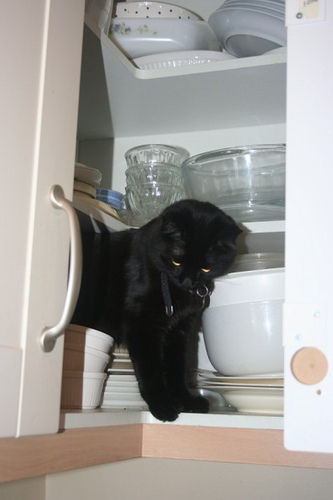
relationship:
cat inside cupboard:
[58, 193, 252, 427] [1, 6, 86, 481]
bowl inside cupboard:
[177, 142, 283, 226] [6, 6, 309, 497]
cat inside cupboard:
[58, 193, 252, 427] [27, 6, 321, 482]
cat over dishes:
[81, 175, 278, 452] [67, 327, 166, 409]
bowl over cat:
[190, 142, 279, 207] [76, 203, 229, 349]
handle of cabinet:
[48, 184, 82, 351] [86, 57, 302, 423]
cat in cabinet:
[58, 193, 252, 427] [1, 0, 332, 482]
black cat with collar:
[70, 199, 245, 421] [158, 270, 209, 316]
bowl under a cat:
[64, 324, 114, 352] [68, 197, 244, 422]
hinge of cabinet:
[289, 341, 320, 386] [38, 30, 312, 382]